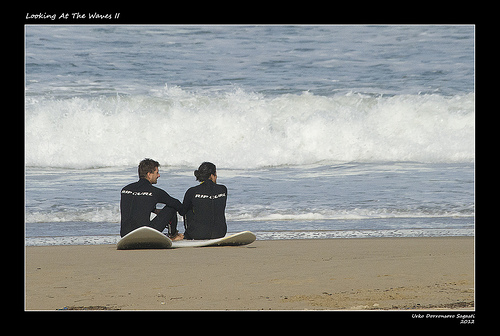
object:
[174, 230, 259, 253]
surfboards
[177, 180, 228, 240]
wetsuits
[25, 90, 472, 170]
wave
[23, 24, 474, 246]
water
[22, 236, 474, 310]
beach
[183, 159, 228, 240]
woman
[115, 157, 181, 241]
man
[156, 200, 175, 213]
knees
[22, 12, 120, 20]
title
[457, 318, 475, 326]
year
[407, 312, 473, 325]
photographer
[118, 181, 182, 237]
wetsuit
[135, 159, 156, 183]
hair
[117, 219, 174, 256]
surfboard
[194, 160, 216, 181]
hair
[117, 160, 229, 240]
couple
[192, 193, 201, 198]
letters